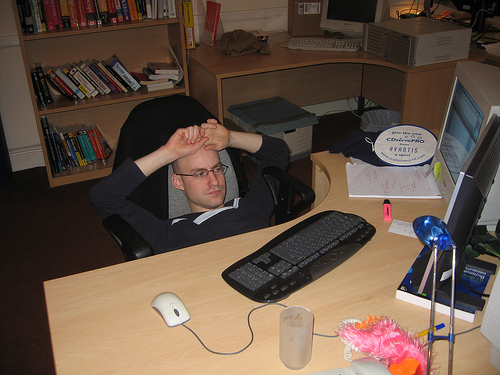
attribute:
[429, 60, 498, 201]
television — small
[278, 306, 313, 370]
glass — empty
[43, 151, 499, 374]
desk — light colored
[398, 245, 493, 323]
texbook — textbook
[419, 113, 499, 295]
monitor — black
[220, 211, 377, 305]
keyboard — black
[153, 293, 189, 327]
mouse — white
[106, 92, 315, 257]
chair — black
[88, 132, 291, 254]
shirt — blue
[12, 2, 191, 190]
book shelf — wooden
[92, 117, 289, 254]
man — sitting, slumping, slouched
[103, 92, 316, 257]
seat — black